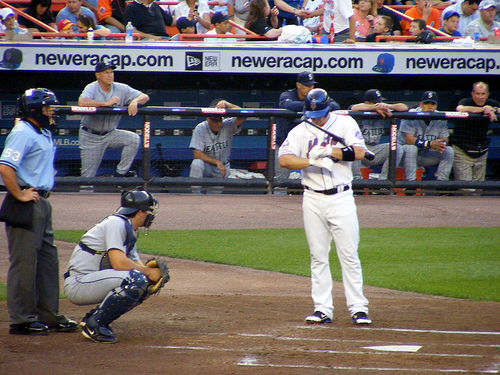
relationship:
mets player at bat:
[272, 78, 392, 330] [296, 113, 394, 160]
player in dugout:
[274, 87, 374, 328] [7, 46, 499, 184]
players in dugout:
[188, 95, 250, 190] [7, 46, 499, 184]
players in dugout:
[351, 82, 395, 191] [7, 46, 499, 184]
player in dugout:
[395, 90, 455, 198] [7, 46, 499, 184]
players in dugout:
[276, 67, 314, 194] [7, 46, 499, 184]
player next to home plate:
[279, 87, 381, 327] [354, 339, 424, 361]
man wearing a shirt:
[0, 89, 73, 332] [35, 146, 58, 193]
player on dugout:
[70, 66, 143, 181] [7, 46, 499, 184]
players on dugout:
[186, 100, 252, 197] [7, 46, 499, 184]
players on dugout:
[349, 89, 409, 197] [7, 46, 499, 184]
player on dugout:
[455, 84, 497, 190] [7, 46, 499, 184]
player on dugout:
[404, 91, 454, 180] [7, 46, 499, 184]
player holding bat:
[279, 87, 381, 327] [298, 115, 375, 162]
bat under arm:
[298, 115, 375, 162] [306, 115, 368, 162]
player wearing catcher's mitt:
[62, 187, 172, 344] [140, 255, 183, 309]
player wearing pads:
[53, 183, 178, 344] [90, 268, 150, 323]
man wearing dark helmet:
[0, 87, 82, 337] [12, 80, 60, 112]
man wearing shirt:
[0, 87, 82, 337] [0, 119, 58, 196]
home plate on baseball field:
[362, 341, 422, 357] [172, 200, 497, 345]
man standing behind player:
[0, 87, 82, 337] [62, 187, 172, 344]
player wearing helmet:
[279, 87, 381, 327] [301, 86, 335, 119]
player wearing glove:
[279, 87, 381, 327] [308, 145, 333, 159]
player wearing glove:
[279, 87, 381, 327] [305, 157, 336, 170]